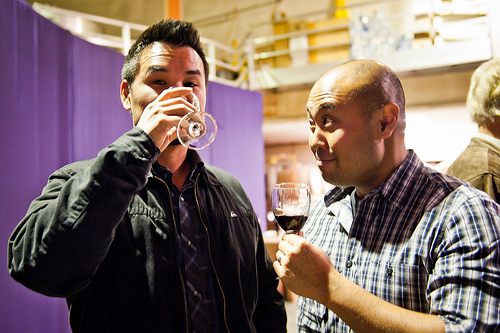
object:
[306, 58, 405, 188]
head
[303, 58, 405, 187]
side view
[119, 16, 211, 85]
spiked hair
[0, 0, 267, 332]
wall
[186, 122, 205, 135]
glass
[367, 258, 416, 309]
shirt pocket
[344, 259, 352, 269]
button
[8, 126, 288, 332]
jacket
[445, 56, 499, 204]
person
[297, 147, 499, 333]
shirt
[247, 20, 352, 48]
rails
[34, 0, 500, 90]
walkway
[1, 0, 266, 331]
purple sheet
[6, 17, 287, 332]
man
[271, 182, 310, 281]
glass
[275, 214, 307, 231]
wine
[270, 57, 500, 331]
man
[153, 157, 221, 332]
blue shirt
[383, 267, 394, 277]
button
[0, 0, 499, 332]
background